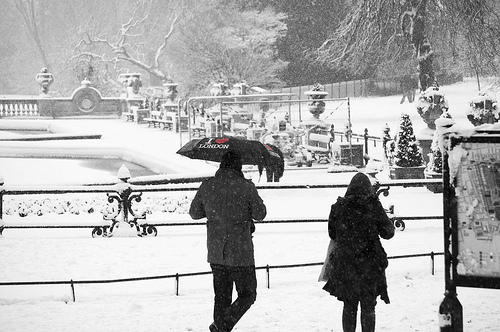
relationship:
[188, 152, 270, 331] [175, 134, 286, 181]
man has umbrella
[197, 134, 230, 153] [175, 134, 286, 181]
words on umbrella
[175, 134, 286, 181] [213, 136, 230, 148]
umbrella has heart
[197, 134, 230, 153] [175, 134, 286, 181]
writing on umbrella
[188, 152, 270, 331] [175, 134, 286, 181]
person has umbrella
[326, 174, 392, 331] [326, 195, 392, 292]
person wearing jacket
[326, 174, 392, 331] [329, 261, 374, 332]
person wearing pants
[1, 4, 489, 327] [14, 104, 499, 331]
snow on ground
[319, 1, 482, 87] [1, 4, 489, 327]
tree covered snow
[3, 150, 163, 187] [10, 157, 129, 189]
water covered in snow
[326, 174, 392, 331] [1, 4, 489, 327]
woman staring at snow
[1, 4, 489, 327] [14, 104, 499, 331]
snow covering ground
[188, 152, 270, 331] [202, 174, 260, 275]
man wearing clothes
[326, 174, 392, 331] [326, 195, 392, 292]
person in coat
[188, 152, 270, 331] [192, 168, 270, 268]
person in coat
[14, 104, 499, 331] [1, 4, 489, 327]
ground covered in snow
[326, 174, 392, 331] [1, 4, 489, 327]
person walking in snow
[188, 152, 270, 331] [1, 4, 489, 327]
person walking in snow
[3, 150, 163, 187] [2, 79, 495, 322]
pond in park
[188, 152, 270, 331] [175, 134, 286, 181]
man holds umbrella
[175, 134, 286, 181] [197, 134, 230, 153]
umbrella has words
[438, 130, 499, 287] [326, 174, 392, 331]
map next to person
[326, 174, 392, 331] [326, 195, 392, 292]
lady wearing coat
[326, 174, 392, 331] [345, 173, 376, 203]
lady wearing hood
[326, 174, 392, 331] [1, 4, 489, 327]
person standing in snow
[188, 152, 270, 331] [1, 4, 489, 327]
person standing in snow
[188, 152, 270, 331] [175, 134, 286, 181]
man holding umbrella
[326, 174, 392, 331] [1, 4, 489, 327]
person in snow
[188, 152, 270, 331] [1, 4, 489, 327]
person in snow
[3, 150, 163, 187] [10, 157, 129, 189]
pond covered in snow